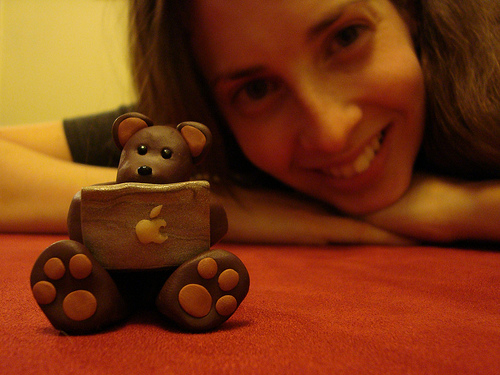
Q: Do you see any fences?
A: No, there are no fences.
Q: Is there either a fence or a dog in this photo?
A: No, there are no fences or dogs.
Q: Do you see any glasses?
A: No, there are no glasses.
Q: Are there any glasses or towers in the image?
A: No, there are no glasses or towers.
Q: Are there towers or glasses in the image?
A: No, there are no glasses or towers.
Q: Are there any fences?
A: No, there are no fences.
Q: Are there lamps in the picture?
A: No, there are no lamps.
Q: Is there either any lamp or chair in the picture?
A: No, there are no lamps or chairs.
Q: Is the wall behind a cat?
A: No, the wall is behind a girl.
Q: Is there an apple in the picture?
A: Yes, there is an apple.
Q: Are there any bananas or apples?
A: Yes, there is an apple.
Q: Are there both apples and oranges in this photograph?
A: No, there is an apple but no oranges.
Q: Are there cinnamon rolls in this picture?
A: No, there are no cinnamon rolls.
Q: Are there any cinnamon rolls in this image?
A: No, there are no cinnamon rolls.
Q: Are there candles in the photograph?
A: No, there are no candles.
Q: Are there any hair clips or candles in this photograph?
A: No, there are no candles or hair clips.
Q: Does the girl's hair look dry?
A: Yes, the hair is dry.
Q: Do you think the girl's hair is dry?
A: Yes, the hair is dry.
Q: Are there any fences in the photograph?
A: No, there are no fences.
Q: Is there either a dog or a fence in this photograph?
A: No, there are no fences or dogs.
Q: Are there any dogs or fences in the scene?
A: No, there are no fences or dogs.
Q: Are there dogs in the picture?
A: No, there are no dogs.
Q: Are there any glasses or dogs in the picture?
A: No, there are no dogs or glasses.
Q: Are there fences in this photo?
A: No, there are no fences.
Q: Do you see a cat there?
A: No, there are no cats.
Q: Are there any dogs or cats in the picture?
A: No, there are no cats or dogs.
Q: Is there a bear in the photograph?
A: Yes, there is a bear.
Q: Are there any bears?
A: Yes, there is a bear.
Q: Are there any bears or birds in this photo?
A: Yes, there is a bear.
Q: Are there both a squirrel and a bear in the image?
A: No, there is a bear but no squirrels.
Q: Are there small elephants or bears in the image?
A: Yes, there is a small bear.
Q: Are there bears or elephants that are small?
A: Yes, the bear is small.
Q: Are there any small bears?
A: Yes, there is a small bear.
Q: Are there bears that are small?
A: Yes, there is a bear that is small.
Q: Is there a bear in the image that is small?
A: Yes, there is a bear that is small.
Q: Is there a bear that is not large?
A: Yes, there is a small bear.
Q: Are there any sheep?
A: No, there are no sheep.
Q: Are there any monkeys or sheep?
A: No, there are no sheep or monkeys.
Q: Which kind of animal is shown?
A: The animal is a bear.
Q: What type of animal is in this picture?
A: The animal is a bear.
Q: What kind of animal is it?
A: The animal is a bear.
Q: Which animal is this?
A: This is a bear.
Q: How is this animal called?
A: This is a bear.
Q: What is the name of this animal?
A: This is a bear.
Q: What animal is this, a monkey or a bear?
A: This is a bear.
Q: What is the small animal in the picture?
A: The animal is a bear.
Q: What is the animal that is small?
A: The animal is a bear.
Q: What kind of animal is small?
A: The animal is a bear.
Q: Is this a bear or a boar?
A: This is a bear.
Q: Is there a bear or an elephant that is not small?
A: No, there is a bear but it is small.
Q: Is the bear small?
A: Yes, the bear is small.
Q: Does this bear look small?
A: Yes, the bear is small.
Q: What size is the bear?
A: The bear is small.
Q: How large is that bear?
A: The bear is small.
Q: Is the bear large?
A: No, the bear is small.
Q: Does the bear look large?
A: No, the bear is small.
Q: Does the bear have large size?
A: No, the bear is small.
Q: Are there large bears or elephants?
A: No, there is a bear but it is small.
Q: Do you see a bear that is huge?
A: No, there is a bear but it is small.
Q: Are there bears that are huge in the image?
A: No, there is a bear but it is small.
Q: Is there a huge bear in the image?
A: No, there is a bear but it is small.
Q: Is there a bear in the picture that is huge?
A: No, there is a bear but it is small.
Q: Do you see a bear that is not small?
A: No, there is a bear but it is small.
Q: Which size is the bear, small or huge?
A: The bear is small.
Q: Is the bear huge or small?
A: The bear is small.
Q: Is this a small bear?
A: Yes, this is a small bear.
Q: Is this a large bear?
A: No, this is a small bear.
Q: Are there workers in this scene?
A: No, there are no workers.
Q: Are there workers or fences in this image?
A: No, there are no workers or fences.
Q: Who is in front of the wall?
A: The girl is in front of the wall.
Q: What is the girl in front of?
A: The girl is in front of the wall.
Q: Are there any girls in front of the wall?
A: Yes, there is a girl in front of the wall.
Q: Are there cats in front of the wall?
A: No, there is a girl in front of the wall.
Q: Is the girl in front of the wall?
A: Yes, the girl is in front of the wall.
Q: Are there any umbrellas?
A: No, there are no umbrellas.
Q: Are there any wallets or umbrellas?
A: No, there are no umbrellas or wallets.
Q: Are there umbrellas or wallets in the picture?
A: No, there are no umbrellas or wallets.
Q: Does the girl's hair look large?
A: Yes, the hair is large.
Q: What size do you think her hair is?
A: The hair is large.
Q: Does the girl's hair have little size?
A: No, the hair is large.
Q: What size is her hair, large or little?
A: The hair is large.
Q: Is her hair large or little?
A: The hair is large.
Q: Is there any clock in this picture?
A: No, there are no clocks.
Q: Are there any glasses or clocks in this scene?
A: No, there are no clocks or glasses.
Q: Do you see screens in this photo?
A: No, there are no screens.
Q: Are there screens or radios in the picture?
A: No, there are no screens or radios.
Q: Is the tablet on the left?
A: Yes, the tablet is on the left of the image.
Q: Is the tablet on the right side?
A: No, the tablet is on the left of the image.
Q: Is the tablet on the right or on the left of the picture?
A: The tablet is on the left of the image.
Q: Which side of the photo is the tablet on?
A: The tablet is on the left of the image.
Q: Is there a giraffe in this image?
A: No, there are no giraffes.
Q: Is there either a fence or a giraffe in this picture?
A: No, there are no giraffes or fences.